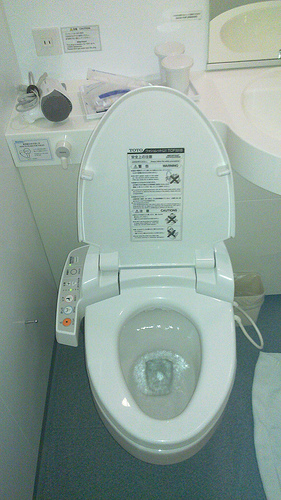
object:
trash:
[231, 270, 262, 326]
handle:
[55, 140, 72, 170]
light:
[119, 397, 129, 406]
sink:
[230, 68, 280, 195]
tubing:
[232, 301, 264, 354]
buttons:
[64, 293, 74, 306]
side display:
[54, 246, 88, 336]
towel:
[251, 350, 281, 499]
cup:
[152, 39, 186, 83]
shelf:
[5, 80, 227, 137]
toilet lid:
[77, 84, 236, 274]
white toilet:
[55, 82, 238, 467]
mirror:
[206, 1, 281, 71]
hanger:
[23, 319, 41, 329]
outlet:
[32, 27, 63, 58]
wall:
[0, 0, 208, 85]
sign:
[60, 24, 103, 56]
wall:
[0, 0, 60, 500]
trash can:
[231, 274, 265, 330]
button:
[61, 304, 73, 314]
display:
[126, 146, 184, 242]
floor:
[33, 293, 281, 499]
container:
[161, 56, 195, 99]